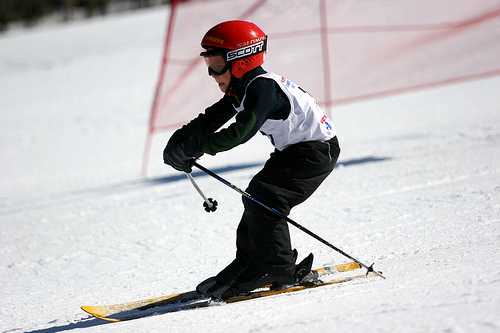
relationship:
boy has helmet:
[156, 11, 353, 309] [196, 19, 273, 83]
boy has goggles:
[156, 11, 353, 309] [193, 35, 272, 80]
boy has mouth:
[156, 11, 353, 309] [212, 78, 231, 89]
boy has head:
[156, 11, 353, 309] [197, 20, 270, 96]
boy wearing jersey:
[156, 11, 353, 309] [223, 73, 342, 154]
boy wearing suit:
[156, 11, 353, 309] [149, 67, 348, 276]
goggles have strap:
[193, 35, 272, 80] [225, 36, 275, 68]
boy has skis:
[156, 11, 353, 309] [65, 253, 382, 327]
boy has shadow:
[156, 11, 353, 309] [0, 279, 217, 333]